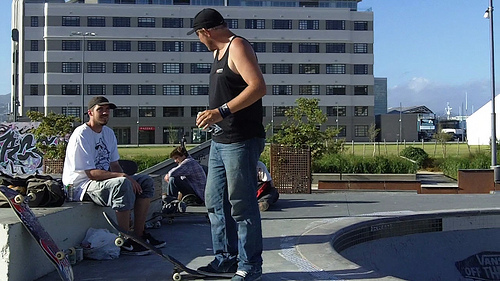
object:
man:
[66, 96, 166, 251]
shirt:
[62, 125, 119, 203]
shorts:
[73, 175, 154, 211]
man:
[185, 8, 276, 280]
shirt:
[203, 36, 265, 145]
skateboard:
[103, 211, 205, 280]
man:
[163, 147, 213, 204]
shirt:
[168, 161, 209, 203]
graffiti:
[0, 125, 45, 174]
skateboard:
[0, 183, 77, 281]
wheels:
[67, 247, 77, 255]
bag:
[82, 226, 122, 260]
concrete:
[0, 184, 500, 281]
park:
[329, 206, 500, 281]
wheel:
[115, 237, 125, 246]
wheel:
[172, 271, 182, 280]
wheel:
[14, 194, 25, 204]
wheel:
[55, 251, 65, 260]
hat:
[184, 7, 225, 36]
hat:
[89, 96, 119, 110]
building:
[14, 4, 376, 144]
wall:
[0, 120, 75, 176]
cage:
[271, 143, 312, 195]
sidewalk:
[249, 181, 500, 207]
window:
[62, 16, 80, 26]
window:
[87, 16, 106, 27]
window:
[112, 17, 132, 28]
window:
[139, 15, 157, 27]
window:
[162, 16, 183, 28]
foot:
[197, 262, 243, 278]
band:
[218, 102, 231, 119]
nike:
[117, 243, 153, 256]